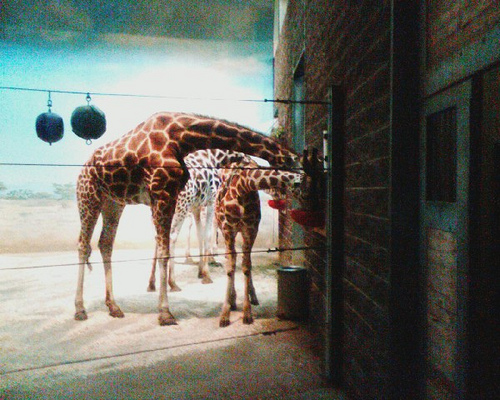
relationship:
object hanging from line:
[69, 102, 106, 140] [0, 84, 335, 106]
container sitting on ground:
[276, 264, 311, 322] [6, 251, 328, 399]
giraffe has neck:
[74, 108, 320, 331] [173, 113, 304, 179]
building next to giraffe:
[272, 37, 499, 399] [74, 108, 320, 331]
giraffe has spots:
[74, 108, 320, 331] [122, 152, 140, 170]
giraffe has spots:
[212, 148, 320, 313] [221, 179, 259, 233]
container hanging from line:
[69, 102, 106, 140] [0, 84, 335, 106]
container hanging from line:
[36, 112, 64, 143] [0, 84, 335, 106]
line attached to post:
[0, 84, 335, 106] [325, 85, 348, 382]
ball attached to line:
[69, 102, 106, 140] [0, 84, 335, 106]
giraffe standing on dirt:
[74, 108, 320, 331] [6, 251, 328, 399]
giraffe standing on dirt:
[212, 148, 320, 313] [6, 251, 328, 399]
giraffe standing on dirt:
[157, 145, 227, 270] [6, 251, 328, 399]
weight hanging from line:
[69, 102, 106, 140] [0, 84, 335, 106]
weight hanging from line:
[36, 112, 64, 143] [0, 74, 335, 114]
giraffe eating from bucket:
[74, 108, 320, 331] [291, 207, 329, 228]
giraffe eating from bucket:
[157, 145, 227, 270] [268, 194, 288, 214]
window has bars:
[422, 108, 459, 204] [428, 110, 460, 201]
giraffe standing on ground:
[74, 108, 320, 331] [6, 251, 328, 399]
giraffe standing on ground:
[212, 148, 320, 313] [6, 251, 328, 399]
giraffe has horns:
[74, 108, 320, 331] [299, 145, 323, 166]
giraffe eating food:
[74, 108, 320, 331] [291, 207, 329, 228]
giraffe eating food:
[212, 148, 320, 313] [291, 207, 329, 228]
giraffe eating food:
[157, 145, 227, 270] [268, 194, 288, 214]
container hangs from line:
[36, 112, 64, 143] [0, 84, 335, 106]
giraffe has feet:
[74, 108, 320, 331] [76, 304, 179, 328]